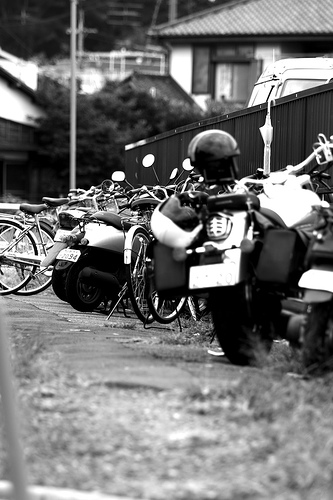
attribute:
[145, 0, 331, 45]
roof — textured 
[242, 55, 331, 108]
van — White 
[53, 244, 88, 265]
license plate — White 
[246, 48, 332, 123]
van — White 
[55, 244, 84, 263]
license plate — White 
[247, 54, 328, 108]
van — White 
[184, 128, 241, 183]
helmet — black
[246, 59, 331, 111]
van — White 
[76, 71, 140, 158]
bushes — green 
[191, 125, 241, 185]
helmet — black 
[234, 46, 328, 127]
van — White 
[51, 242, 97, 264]
license plate — White 